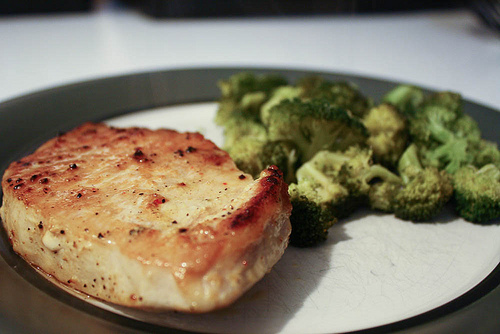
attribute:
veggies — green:
[229, 68, 326, 150]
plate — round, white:
[338, 227, 489, 321]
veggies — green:
[342, 84, 418, 152]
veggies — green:
[296, 142, 367, 232]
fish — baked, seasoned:
[32, 124, 271, 311]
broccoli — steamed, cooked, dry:
[269, 98, 361, 157]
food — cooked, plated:
[120, 104, 381, 239]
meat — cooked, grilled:
[153, 163, 237, 293]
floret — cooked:
[287, 183, 313, 226]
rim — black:
[438, 279, 495, 330]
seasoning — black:
[68, 145, 155, 179]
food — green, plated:
[252, 72, 479, 239]